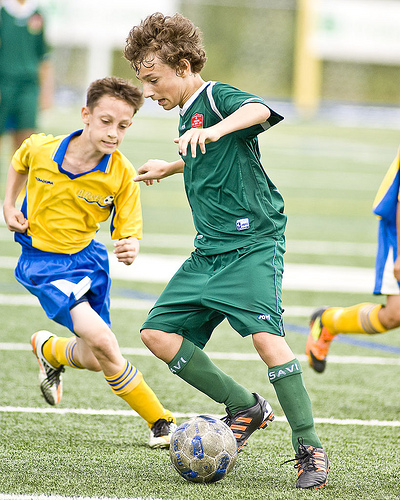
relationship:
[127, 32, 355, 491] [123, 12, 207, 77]
boy has brown boy's hair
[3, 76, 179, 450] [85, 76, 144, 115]
boy has short boy's hair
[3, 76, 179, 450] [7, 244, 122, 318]
boy wearing shorts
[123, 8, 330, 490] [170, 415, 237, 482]
boy kicking ball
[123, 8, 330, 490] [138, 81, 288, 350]
boy in a soccer uniform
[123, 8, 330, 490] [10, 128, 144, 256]
boy in a soccer uniform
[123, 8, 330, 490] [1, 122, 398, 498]
boy running on grass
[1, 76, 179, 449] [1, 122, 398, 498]
boy running on grass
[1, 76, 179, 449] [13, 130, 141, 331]
boy wearing a uniform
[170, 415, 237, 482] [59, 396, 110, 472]
ball on grass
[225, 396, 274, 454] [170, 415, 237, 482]
cleats used for ball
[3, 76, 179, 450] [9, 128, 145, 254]
boy wearing a jersey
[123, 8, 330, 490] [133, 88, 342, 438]
boy wearing a uniform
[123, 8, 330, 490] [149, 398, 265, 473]
boy kicking soccer ball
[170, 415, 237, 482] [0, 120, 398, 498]
ball playing with ground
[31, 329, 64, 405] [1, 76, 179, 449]
cleats on boy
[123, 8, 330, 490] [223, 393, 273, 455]
boy wearing cleats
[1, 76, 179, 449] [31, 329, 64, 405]
boy wearing cleats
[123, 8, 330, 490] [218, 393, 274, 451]
boy wearing cleat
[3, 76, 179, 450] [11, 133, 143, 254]
boy wearing jersey